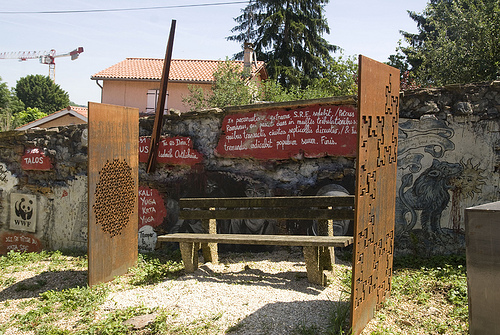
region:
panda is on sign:
[12, 190, 42, 233]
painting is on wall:
[400, 121, 478, 248]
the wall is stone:
[197, 105, 498, 210]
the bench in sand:
[165, 186, 333, 295]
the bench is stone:
[172, 190, 337, 284]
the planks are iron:
[82, 104, 147, 285]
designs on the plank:
[355, 62, 410, 308]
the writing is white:
[225, 119, 327, 148]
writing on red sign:
[223, 112, 354, 157]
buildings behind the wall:
[85, 51, 287, 176]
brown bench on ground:
[153, 195, 354, 287]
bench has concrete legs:
[179, 240, 199, 272]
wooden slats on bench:
[177, 196, 355, 208]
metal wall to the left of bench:
[87, 103, 142, 285]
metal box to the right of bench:
[464, 201, 499, 333]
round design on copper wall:
[95, 155, 137, 235]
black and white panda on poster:
[8, 192, 35, 232]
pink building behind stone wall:
[88, 55, 268, 110]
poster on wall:
[7, 190, 37, 230]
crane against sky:
[1, 45, 92, 82]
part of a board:
[80, 116, 122, 161]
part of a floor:
[206, 270, 234, 292]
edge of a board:
[333, 268, 361, 323]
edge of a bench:
[266, 232, 302, 262]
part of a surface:
[341, 200, 405, 287]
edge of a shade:
[258, 301, 272, 313]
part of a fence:
[434, 112, 470, 167]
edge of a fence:
[404, 57, 465, 114]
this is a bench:
[178, 198, 333, 265]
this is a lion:
[405, 172, 445, 218]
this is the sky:
[63, 19, 115, 51]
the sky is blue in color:
[91, 25, 131, 53]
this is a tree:
[258, 19, 303, 51]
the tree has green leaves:
[287, 29, 302, 52]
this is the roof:
[123, 55, 189, 84]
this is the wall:
[114, 83, 128, 100]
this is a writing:
[228, 115, 340, 144]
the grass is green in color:
[45, 286, 90, 316]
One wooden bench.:
[154, 177, 353, 287]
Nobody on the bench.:
[152, 177, 346, 284]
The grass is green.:
[0, 237, 476, 327]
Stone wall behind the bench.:
[9, 130, 499, 265]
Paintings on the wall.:
[14, 119, 461, 274]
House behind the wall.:
[66, 40, 287, 115]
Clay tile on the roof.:
[96, 39, 278, 92]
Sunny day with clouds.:
[14, 3, 432, 111]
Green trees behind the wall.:
[194, 20, 495, 106]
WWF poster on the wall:
[4, 185, 45, 241]